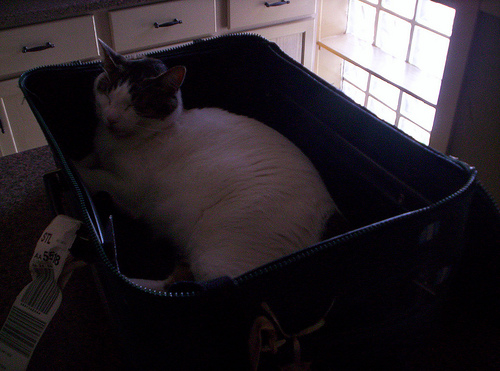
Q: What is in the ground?
A: Cat.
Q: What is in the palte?
A: Cat.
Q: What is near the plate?
A: Cat.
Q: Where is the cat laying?
A: Box.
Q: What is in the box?
A: Cat.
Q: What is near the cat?
A: Windows.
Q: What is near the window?
A: Cat.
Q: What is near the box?
A: Windows.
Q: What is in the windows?
A: Metal.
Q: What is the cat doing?
A: Sleeping.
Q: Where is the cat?
A: Suitcase.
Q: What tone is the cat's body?
A: White.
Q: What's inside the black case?
A: Cat.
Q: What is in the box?
A: Cat.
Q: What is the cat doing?
A: Laying.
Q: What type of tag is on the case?
A: Baggage claim.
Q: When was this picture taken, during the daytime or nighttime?
A: Daytime.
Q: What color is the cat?
A: Black and white.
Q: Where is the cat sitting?
A: Suitcase.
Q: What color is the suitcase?
A: Blue.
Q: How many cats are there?
A: One.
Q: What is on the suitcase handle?
A: Tag.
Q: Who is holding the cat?
A: No one.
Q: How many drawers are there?
A: Three.